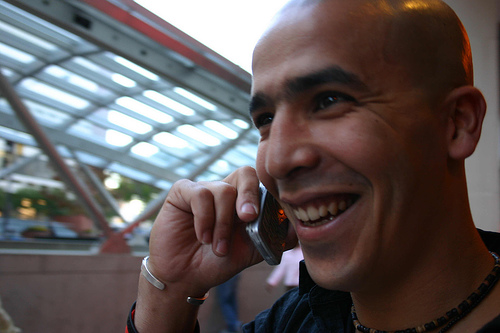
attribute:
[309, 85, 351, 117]
eye — looking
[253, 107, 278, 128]
eye — looking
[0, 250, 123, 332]
wall — concrete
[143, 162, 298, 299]
hand — man's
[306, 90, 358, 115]
eye — brown 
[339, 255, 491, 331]
necklace — brown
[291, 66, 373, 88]
eyebrows — heavy, dark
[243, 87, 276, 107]
eyebrows — heavy, dark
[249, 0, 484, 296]
head — shaved, polished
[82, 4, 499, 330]
stranger — happy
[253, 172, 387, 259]
mouth — smiling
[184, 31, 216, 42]
nothing — clear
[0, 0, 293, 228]
sky — clear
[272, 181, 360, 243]
smile — big